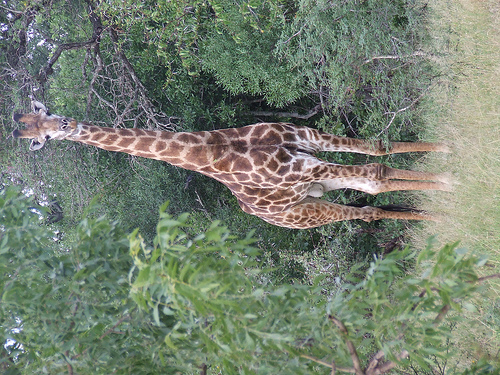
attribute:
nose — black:
[55, 112, 80, 131]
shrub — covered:
[118, 200, 499, 374]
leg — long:
[292, 120, 459, 153]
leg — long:
[302, 157, 459, 184]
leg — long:
[324, 182, 455, 195]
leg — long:
[314, 200, 433, 223]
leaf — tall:
[173, 26, 220, 72]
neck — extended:
[77, 120, 221, 183]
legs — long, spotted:
[263, 119, 458, 186]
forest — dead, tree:
[3, 0, 495, 374]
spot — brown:
[211, 151, 232, 174]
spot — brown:
[245, 146, 279, 169]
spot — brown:
[230, 136, 249, 157]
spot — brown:
[216, 126, 249, 141]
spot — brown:
[187, 146, 208, 167]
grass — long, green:
[407, 8, 498, 273]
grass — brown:
[375, 0, 497, 369]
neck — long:
[63, 118, 214, 175]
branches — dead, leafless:
[9, 37, 167, 139]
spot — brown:
[132, 137, 156, 151]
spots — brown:
[225, 134, 290, 178]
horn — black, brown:
[10, 112, 33, 122]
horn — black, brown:
[12, 124, 31, 138]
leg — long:
[341, 137, 429, 157]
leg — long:
[324, 161, 411, 181]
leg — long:
[347, 180, 407, 194]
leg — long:
[332, 202, 421, 228]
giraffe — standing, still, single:
[9, 87, 462, 235]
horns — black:
[16, 109, 31, 129]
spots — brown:
[221, 154, 261, 195]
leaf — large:
[194, 258, 244, 297]